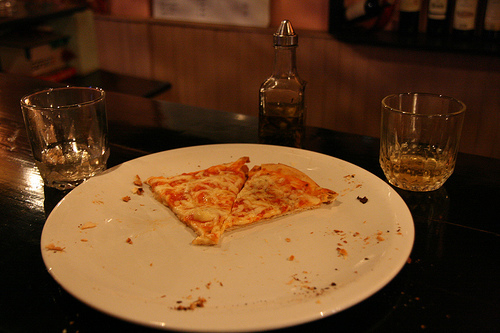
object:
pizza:
[146, 153, 248, 247]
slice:
[228, 161, 336, 227]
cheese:
[176, 181, 226, 222]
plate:
[40, 142, 416, 332]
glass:
[378, 91, 467, 192]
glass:
[255, 20, 307, 150]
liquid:
[379, 145, 456, 191]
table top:
[0, 111, 498, 332]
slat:
[95, 14, 279, 38]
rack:
[326, 0, 499, 68]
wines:
[479, 0, 500, 38]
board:
[145, 0, 271, 32]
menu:
[151, 2, 269, 29]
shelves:
[0, 27, 80, 95]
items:
[0, 27, 80, 84]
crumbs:
[285, 253, 298, 262]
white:
[102, 245, 177, 301]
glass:
[20, 86, 112, 191]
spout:
[270, 19, 301, 48]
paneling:
[147, 19, 499, 155]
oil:
[256, 104, 307, 149]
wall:
[90, 12, 500, 160]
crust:
[146, 155, 249, 186]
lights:
[0, 0, 119, 22]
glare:
[16, 160, 45, 213]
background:
[0, 0, 499, 332]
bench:
[59, 69, 174, 100]